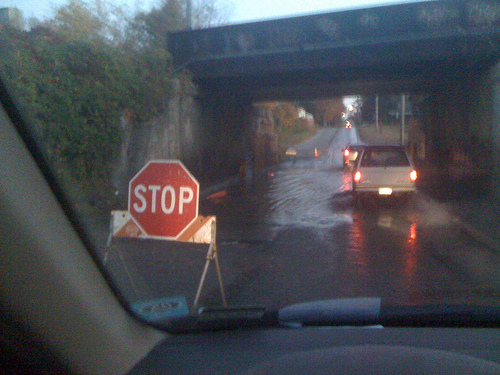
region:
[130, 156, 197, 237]
a white and red sign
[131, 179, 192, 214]
white letters on a sign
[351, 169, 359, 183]
tail light of a car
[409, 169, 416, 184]
tail light of a car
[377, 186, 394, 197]
license plate of a car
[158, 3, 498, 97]
top of a metal bridge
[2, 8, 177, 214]
shrubs on concrete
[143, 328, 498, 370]
the dashboard of a car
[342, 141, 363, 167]
a car is brakeing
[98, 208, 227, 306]
a white and orange barrier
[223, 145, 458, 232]
Cars driving through a puddle of water.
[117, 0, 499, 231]
Water under a bridge.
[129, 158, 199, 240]
A red and white stop sign.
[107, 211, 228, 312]
A white and orange striped traffic stand.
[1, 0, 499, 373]
Dashboard and glass front window.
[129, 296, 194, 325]
Sticker on the lower part of the car window.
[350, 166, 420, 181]
Tail lights on the back of a jeep.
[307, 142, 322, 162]
Orange traffic cone in the road.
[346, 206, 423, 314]
Tail lights reflecting off of the water.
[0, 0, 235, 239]
Brush growing along the side of the bridge.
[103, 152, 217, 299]
a red and white street sign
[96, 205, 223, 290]
a orange and white barricade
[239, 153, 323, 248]
water covering the road way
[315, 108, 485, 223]
a car driving through water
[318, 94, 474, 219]
a car driving under a bridge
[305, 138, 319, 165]
a orange and white caution cone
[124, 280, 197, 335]
a sticker in a windshield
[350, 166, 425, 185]
tail lights on a vehicle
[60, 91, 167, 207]
grass and vines growing next to a bridge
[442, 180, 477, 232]
a concrete sidewalk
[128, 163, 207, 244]
Red sign attached to construction sign.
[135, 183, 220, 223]
White lettering on red sign.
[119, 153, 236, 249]
White outline on red sign.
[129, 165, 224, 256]
Red sign has 8 sides.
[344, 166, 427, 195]
Red lights on back of car.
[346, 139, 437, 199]
White vehicle driving on road.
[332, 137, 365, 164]
Vehicle driving on road.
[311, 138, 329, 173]
Orange and white construction cone in road.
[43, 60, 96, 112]
Green leaves on branches.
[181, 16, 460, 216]
Cars going under bridge.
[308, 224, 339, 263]
part of a window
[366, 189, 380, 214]
part of a glass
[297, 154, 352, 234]
part of a window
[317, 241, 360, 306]
part of a window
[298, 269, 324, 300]
part of a window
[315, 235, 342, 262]
part of a flood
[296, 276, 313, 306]
par tof a windoe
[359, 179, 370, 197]
edge of a car